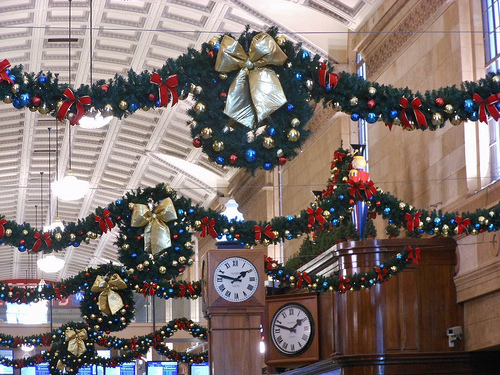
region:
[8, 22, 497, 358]
christmas decorations are hanging over the floor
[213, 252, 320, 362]
clocks are in the building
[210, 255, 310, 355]
the face of the clocks is white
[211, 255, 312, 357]
the hands of the clocks are black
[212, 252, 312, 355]
roman numerals are on the clocks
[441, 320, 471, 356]
a video camera is on the wall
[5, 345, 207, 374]
monitors are lined up on the floor of the building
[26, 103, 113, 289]
light fixtures are hanging from the ceiling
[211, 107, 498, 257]
large windows are in the building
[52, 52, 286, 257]
a bunch of christmas decorations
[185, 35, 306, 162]
a really big christmas wreath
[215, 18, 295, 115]
a big golden bow decoration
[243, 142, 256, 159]
a shiny blue christmas ornament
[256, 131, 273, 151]
a shiny gold christmas ornament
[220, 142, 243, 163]
a shiny red christmas ornament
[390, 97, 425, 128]
a tiny red christmas bow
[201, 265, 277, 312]
a small roman numeral clock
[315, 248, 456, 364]
a big wooden staircase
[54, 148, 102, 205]
a light dangling down from the ceiling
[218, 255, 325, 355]
two roman letter clock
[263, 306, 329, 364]
a circle shape clock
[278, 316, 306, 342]
two needles in the roman letter clock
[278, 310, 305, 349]
white background of the clock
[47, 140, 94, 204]
a lamp hanging from the ceiling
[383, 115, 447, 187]
brown color wall tiles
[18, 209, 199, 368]
a place decorated with some materials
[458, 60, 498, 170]
window of the building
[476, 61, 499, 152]
window made with glass and steel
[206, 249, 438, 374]
wooden cupboard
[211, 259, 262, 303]
a clock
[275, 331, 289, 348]
roman numerials on the clock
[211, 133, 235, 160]
ornaments on the reff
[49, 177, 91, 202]
a light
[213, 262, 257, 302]
the clock is white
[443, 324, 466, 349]
a camera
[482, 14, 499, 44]
a window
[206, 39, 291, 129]
a bow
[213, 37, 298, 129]
a golden bow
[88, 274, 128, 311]
the bow on the reff is gold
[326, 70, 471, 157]
christmas ball hanging from the ceiling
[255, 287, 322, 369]
the clock face is white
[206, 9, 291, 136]
the bow is gold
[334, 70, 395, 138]
the balls are red, gold, and blue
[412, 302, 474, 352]
a camera on the wall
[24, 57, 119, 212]
lights hanging from the ceiling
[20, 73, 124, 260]
the lights are on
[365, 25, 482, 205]
the walls are beige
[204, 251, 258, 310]
the numbers are roman numerals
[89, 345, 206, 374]
the computers are on